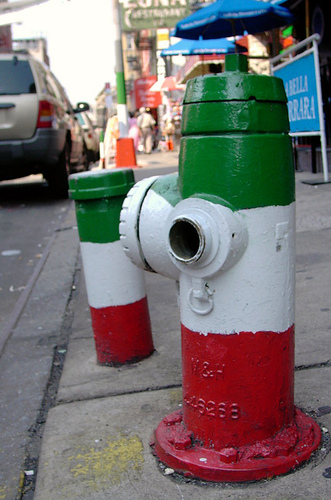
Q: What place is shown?
A: It is a sidewalk.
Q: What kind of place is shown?
A: It is a sidewalk.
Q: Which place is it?
A: It is a sidewalk.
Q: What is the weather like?
A: It is cloudy.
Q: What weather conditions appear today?
A: It is cloudy.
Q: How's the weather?
A: It is cloudy.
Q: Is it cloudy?
A: Yes, it is cloudy.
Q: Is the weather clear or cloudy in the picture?
A: It is cloudy.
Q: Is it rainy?
A: No, it is cloudy.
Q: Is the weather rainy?
A: No, it is cloudy.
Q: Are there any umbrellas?
A: Yes, there is an umbrella.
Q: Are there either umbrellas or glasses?
A: Yes, there is an umbrella.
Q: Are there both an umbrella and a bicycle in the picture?
A: No, there is an umbrella but no bicycles.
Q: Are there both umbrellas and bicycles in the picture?
A: No, there is an umbrella but no bicycles.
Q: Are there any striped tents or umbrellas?
A: Yes, there is a striped umbrella.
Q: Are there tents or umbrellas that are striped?
A: Yes, the umbrella is striped.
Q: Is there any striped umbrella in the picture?
A: Yes, there is a striped umbrella.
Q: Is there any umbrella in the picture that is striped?
A: Yes, there is an umbrella that is striped.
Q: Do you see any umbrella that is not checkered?
A: Yes, there is a striped umbrella.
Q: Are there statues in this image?
A: No, there are no statues.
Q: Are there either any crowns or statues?
A: No, there are no statues or crowns.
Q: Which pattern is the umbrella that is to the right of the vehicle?
A: The umbrella is striped.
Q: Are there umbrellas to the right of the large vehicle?
A: Yes, there is an umbrella to the right of the vehicle.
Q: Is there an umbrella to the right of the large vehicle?
A: Yes, there is an umbrella to the right of the vehicle.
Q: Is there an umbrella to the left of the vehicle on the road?
A: No, the umbrella is to the right of the vehicle.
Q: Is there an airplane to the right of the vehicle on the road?
A: No, there is an umbrella to the right of the vehicle.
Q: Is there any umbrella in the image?
A: Yes, there is an umbrella.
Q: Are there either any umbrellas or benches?
A: Yes, there is an umbrella.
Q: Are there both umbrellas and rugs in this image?
A: No, there is an umbrella but no rugs.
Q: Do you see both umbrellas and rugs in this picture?
A: No, there is an umbrella but no rugs.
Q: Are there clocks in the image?
A: No, there are no clocks.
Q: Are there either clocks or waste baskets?
A: No, there are no clocks or waste baskets.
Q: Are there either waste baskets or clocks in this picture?
A: No, there are no clocks or waste baskets.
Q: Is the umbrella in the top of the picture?
A: Yes, the umbrella is in the top of the image.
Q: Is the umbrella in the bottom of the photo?
A: No, the umbrella is in the top of the image.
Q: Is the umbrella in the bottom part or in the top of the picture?
A: The umbrella is in the top of the image.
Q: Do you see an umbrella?
A: Yes, there is an umbrella.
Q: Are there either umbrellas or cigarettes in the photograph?
A: Yes, there is an umbrella.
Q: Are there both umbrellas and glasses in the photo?
A: No, there is an umbrella but no glasses.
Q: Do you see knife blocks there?
A: No, there are no knife blocks.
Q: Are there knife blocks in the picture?
A: No, there are no knife blocks.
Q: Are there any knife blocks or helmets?
A: No, there are no knife blocks or helmets.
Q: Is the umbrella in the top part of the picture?
A: Yes, the umbrella is in the top of the image.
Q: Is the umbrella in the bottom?
A: No, the umbrella is in the top of the image.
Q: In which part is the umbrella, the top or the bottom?
A: The umbrella is in the top of the image.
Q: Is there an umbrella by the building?
A: Yes, there is an umbrella by the building.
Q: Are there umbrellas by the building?
A: Yes, there is an umbrella by the building.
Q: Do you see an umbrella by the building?
A: Yes, there is an umbrella by the building.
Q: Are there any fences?
A: No, there are no fences.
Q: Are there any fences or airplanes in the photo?
A: No, there are no fences or airplanes.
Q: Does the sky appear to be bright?
A: Yes, the sky is bright.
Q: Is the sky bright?
A: Yes, the sky is bright.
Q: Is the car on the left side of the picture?
A: Yes, the car is on the left of the image.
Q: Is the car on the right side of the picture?
A: No, the car is on the left of the image.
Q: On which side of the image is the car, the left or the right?
A: The car is on the left of the image.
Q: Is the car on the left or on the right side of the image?
A: The car is on the left of the image.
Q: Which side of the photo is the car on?
A: The car is on the left of the image.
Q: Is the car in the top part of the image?
A: Yes, the car is in the top of the image.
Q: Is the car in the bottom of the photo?
A: No, the car is in the top of the image.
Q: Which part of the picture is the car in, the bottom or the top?
A: The car is in the top of the image.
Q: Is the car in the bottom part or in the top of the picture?
A: The car is in the top of the image.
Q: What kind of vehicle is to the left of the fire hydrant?
A: The vehicle is a car.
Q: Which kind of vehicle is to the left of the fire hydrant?
A: The vehicle is a car.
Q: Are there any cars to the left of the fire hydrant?
A: Yes, there is a car to the left of the fire hydrant.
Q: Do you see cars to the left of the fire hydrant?
A: Yes, there is a car to the left of the fire hydrant.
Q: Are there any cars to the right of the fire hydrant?
A: No, the car is to the left of the fire hydrant.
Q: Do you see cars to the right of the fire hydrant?
A: No, the car is to the left of the fire hydrant.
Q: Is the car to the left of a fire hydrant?
A: Yes, the car is to the left of a fire hydrant.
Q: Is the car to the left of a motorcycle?
A: No, the car is to the left of a fire hydrant.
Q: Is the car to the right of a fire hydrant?
A: No, the car is to the left of a fire hydrant.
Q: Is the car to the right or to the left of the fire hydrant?
A: The car is to the left of the fire hydrant.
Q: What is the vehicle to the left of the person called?
A: The vehicle is a car.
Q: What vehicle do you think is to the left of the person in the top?
A: The vehicle is a car.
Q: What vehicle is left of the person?
A: The vehicle is a car.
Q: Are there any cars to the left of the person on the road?
A: Yes, there is a car to the left of the person.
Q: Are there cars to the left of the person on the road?
A: Yes, there is a car to the left of the person.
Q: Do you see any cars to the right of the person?
A: No, the car is to the left of the person.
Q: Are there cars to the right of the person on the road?
A: No, the car is to the left of the person.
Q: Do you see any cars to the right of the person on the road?
A: No, the car is to the left of the person.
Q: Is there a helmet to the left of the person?
A: No, there is a car to the left of the person.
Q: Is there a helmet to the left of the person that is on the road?
A: No, there is a car to the left of the person.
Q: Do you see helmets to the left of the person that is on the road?
A: No, there is a car to the left of the person.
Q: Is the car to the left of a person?
A: Yes, the car is to the left of a person.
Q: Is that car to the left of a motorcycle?
A: No, the car is to the left of a person.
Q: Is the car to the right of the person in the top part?
A: No, the car is to the left of the person.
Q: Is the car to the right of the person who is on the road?
A: No, the car is to the left of the person.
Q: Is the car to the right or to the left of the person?
A: The car is to the left of the person.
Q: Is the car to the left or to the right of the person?
A: The car is to the left of the person.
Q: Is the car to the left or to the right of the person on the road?
A: The car is to the left of the person.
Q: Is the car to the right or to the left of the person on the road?
A: The car is to the left of the person.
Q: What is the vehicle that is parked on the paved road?
A: The vehicle is a car.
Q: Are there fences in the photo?
A: No, there are no fences.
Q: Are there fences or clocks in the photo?
A: No, there are no fences or clocks.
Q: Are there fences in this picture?
A: No, there are no fences.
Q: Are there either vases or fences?
A: No, there are no fences or vases.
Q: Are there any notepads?
A: No, there are no notepads.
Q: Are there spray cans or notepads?
A: No, there are no notepads or spray cans.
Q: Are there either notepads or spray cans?
A: No, there are no notepads or spray cans.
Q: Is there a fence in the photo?
A: No, there are no fences.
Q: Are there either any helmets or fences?
A: No, there are no fences or helmets.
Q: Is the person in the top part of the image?
A: Yes, the person is in the top of the image.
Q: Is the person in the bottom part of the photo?
A: No, the person is in the top of the image.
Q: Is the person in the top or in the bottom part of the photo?
A: The person is in the top of the image.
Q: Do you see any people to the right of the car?
A: Yes, there is a person to the right of the car.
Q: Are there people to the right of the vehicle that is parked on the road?
A: Yes, there is a person to the right of the car.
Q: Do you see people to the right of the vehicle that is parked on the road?
A: Yes, there is a person to the right of the car.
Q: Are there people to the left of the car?
A: No, the person is to the right of the car.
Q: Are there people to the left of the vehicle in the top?
A: No, the person is to the right of the car.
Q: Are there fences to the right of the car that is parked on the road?
A: No, there is a person to the right of the car.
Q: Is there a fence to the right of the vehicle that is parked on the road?
A: No, there is a person to the right of the car.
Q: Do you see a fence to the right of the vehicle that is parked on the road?
A: No, there is a person to the right of the car.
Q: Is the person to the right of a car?
A: Yes, the person is to the right of a car.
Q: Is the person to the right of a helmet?
A: No, the person is to the right of a car.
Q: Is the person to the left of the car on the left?
A: No, the person is to the right of the car.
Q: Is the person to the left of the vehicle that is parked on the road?
A: No, the person is to the right of the car.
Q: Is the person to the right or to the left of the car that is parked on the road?
A: The person is to the right of the car.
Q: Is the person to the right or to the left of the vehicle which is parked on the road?
A: The person is to the right of the car.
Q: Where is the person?
A: The person is on the road.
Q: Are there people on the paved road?
A: Yes, there is a person on the road.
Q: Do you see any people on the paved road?
A: Yes, there is a person on the road.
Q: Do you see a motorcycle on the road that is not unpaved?
A: No, there is a person on the road.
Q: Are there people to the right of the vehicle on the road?
A: Yes, there is a person to the right of the vehicle.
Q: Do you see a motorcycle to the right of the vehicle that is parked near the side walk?
A: No, there is a person to the right of the vehicle.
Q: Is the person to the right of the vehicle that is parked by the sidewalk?
A: Yes, the person is to the right of the vehicle.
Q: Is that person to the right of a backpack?
A: No, the person is to the right of the vehicle.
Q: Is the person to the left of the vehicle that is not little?
A: No, the person is to the right of the vehicle.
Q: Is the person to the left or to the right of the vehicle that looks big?
A: The person is to the right of the vehicle.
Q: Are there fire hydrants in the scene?
A: Yes, there is a fire hydrant.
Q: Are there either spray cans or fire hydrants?
A: Yes, there is a fire hydrant.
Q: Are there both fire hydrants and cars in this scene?
A: Yes, there are both a fire hydrant and a car.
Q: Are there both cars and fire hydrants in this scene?
A: Yes, there are both a fire hydrant and a car.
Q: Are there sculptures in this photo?
A: No, there are no sculptures.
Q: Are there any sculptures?
A: No, there are no sculptures.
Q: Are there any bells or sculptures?
A: No, there are no sculptures or bells.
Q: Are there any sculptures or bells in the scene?
A: No, there are no sculptures or bells.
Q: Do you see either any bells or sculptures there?
A: No, there are no sculptures or bells.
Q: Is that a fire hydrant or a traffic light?
A: That is a fire hydrant.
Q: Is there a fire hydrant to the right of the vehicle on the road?
A: Yes, there is a fire hydrant to the right of the vehicle.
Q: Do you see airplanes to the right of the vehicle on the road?
A: No, there is a fire hydrant to the right of the vehicle.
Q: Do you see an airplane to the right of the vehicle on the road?
A: No, there is a fire hydrant to the right of the vehicle.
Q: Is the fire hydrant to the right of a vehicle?
A: Yes, the fire hydrant is to the right of a vehicle.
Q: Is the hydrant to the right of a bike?
A: No, the hydrant is to the right of a vehicle.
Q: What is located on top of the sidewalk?
A: The fire hydrant is on top of the sidewalk.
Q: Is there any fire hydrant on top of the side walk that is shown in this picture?
A: Yes, there is a fire hydrant on top of the side walk.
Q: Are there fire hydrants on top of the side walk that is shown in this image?
A: Yes, there is a fire hydrant on top of the side walk.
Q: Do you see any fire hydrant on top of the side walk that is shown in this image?
A: Yes, there is a fire hydrant on top of the side walk.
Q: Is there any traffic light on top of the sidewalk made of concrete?
A: No, there is a fire hydrant on top of the sidewalk.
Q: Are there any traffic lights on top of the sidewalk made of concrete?
A: No, there is a fire hydrant on top of the sidewalk.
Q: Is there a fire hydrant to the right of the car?
A: Yes, there is a fire hydrant to the right of the car.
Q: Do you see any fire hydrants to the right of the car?
A: Yes, there is a fire hydrant to the right of the car.